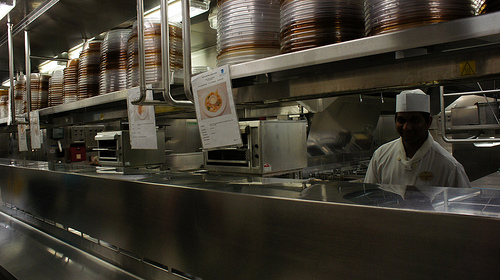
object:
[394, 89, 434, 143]
head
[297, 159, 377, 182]
vats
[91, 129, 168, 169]
oven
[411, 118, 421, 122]
eye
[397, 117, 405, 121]
eye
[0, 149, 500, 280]
counter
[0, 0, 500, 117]
shelving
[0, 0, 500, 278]
kitchen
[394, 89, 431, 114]
cap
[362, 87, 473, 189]
cook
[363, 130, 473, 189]
shirt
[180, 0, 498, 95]
shelf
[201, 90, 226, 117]
plate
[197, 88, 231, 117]
picture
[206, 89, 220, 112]
food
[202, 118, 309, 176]
microwave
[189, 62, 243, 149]
instructions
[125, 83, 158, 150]
instructions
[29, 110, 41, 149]
instructions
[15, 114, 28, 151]
instructions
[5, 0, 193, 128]
shelf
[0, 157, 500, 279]
shelf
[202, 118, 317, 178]
kitchen oven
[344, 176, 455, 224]
reflection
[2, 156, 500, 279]
steel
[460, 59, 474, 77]
triangle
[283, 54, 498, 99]
steel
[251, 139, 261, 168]
knob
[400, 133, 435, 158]
neck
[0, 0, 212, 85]
lights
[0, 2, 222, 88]
ceiling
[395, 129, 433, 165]
scarf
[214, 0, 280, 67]
stack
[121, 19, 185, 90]
stack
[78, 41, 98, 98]
stack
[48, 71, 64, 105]
stack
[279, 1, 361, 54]
stack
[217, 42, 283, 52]
plate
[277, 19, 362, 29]
plate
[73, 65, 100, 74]
plate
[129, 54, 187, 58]
plate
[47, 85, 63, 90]
plate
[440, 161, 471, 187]
arm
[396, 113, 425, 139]
face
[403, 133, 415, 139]
mouth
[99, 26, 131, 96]
containers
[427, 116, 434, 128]
ear